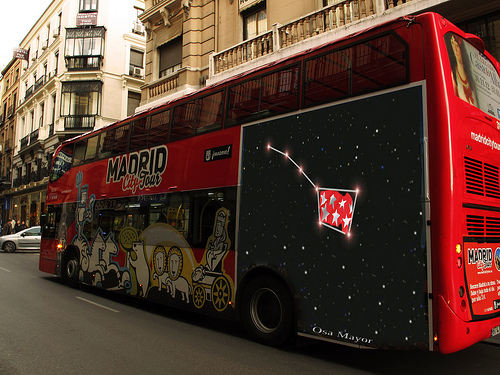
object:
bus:
[38, 11, 499, 354]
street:
[0, 250, 500, 375]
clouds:
[0, 0, 52, 80]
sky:
[0, 0, 55, 73]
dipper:
[264, 144, 358, 240]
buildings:
[0, 52, 22, 232]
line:
[75, 297, 119, 312]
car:
[0, 224, 42, 253]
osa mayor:
[311, 325, 372, 344]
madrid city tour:
[104, 145, 169, 192]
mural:
[234, 84, 425, 349]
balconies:
[238, 0, 267, 47]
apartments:
[14, 0, 142, 233]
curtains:
[65, 38, 74, 56]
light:
[454, 242, 464, 252]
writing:
[153, 145, 166, 172]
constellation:
[304, 272, 308, 274]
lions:
[164, 246, 190, 303]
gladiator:
[73, 185, 88, 245]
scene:
[0, 0, 498, 375]